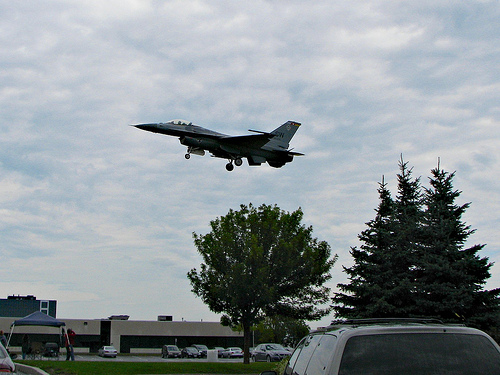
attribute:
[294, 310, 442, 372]
van — gray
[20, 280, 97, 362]
tent — blue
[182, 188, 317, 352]
tree — planted, here, green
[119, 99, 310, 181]
jet — flying, grey, white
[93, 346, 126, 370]
car — parked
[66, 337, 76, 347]
shirt — red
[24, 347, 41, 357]
shirt — gray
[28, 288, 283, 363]
building — long, brown, grey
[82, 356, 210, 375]
grass — here, green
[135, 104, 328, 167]
airplane — here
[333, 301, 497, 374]
window — here, black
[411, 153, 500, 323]
evergreen — small cluster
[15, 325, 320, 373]
parking lot — narrow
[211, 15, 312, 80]
cloud — cloudy 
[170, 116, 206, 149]
pilot — here